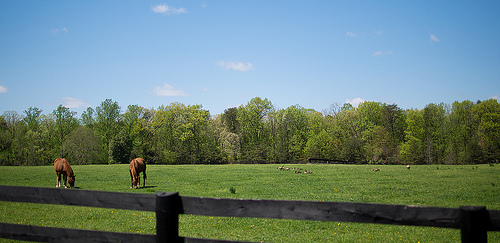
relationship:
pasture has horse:
[0, 162, 499, 241] [125, 156, 147, 187]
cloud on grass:
[343, 97, 363, 109] [150, 159, 257, 201]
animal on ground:
[53, 157, 77, 189] [48, 167, 208, 195]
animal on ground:
[129, 157, 147, 189] [48, 167, 208, 195]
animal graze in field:
[129, 157, 147, 189] [51, 96, 427, 227]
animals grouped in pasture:
[274, 160, 315, 178] [2, 153, 497, 240]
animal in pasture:
[127, 154, 149, 191] [0, 162, 499, 241]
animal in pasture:
[48, 157, 78, 193] [0, 162, 499, 241]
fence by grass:
[6, 184, 497, 239] [347, 170, 408, 197]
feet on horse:
[55, 182, 62, 187] [49, 156, 76, 188]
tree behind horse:
[182, 107, 207, 157] [75, 139, 157, 222]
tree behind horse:
[245, 100, 285, 158] [75, 139, 157, 222]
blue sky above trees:
[0, 0, 498, 121] [0, 95, 499, 163]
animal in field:
[129, 157, 147, 189] [0, 158, 500, 235]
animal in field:
[53, 157, 77, 189] [64, 84, 469, 241]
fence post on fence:
[154, 189, 181, 241] [0, 172, 497, 241]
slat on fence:
[182, 194, 466, 225] [6, 184, 497, 239]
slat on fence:
[4, 185, 169, 213] [0, 178, 500, 240]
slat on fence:
[183, 193, 477, 231] [0, 178, 500, 240]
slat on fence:
[0, 229, 107, 240] [0, 178, 500, 240]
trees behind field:
[307, 95, 479, 162] [19, 161, 429, 220]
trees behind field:
[47, 96, 254, 158] [19, 161, 429, 220]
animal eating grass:
[129, 157, 147, 189] [126, 182, 145, 195]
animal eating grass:
[129, 157, 147, 189] [134, 177, 175, 201]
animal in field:
[129, 157, 147, 189] [2, 162, 499, 240]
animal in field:
[53, 157, 77, 189] [2, 162, 499, 240]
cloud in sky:
[216, 58, 256, 73] [3, 2, 498, 125]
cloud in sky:
[150, 0, 192, 13] [3, 2, 498, 125]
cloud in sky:
[331, 94, 364, 109] [3, 2, 498, 125]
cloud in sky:
[60, 94, 92, 108] [3, 2, 498, 125]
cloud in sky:
[0, 82, 8, 94] [3, 2, 498, 125]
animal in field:
[53, 157, 77, 189] [9, 174, 182, 225]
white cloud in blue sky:
[159, 84, 188, 97] [4, 2, 194, 106]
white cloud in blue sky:
[213, 54, 243, 74] [4, 2, 194, 106]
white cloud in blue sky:
[145, 2, 172, 12] [4, 2, 194, 106]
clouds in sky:
[151, 58, 256, 102] [3, 2, 498, 125]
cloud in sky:
[207, 47, 262, 79] [3, 2, 498, 125]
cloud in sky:
[142, 0, 197, 20] [3, 2, 498, 125]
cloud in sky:
[148, 77, 190, 100] [3, 2, 498, 125]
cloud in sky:
[426, 30, 444, 47] [3, 2, 498, 125]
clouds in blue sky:
[133, 13, 350, 125] [3, 2, 253, 111]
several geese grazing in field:
[276, 163, 408, 174] [0, 163, 498, 210]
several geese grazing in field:
[276, 163, 408, 174] [179, 213, 459, 241]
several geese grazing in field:
[276, 163, 408, 174] [2, 201, 155, 233]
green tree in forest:
[310, 114, 349, 165] [3, 101, 498, 166]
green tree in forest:
[45, 109, 80, 156] [3, 101, 498, 166]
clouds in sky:
[213, 54, 263, 76] [0, 0, 499, 94]